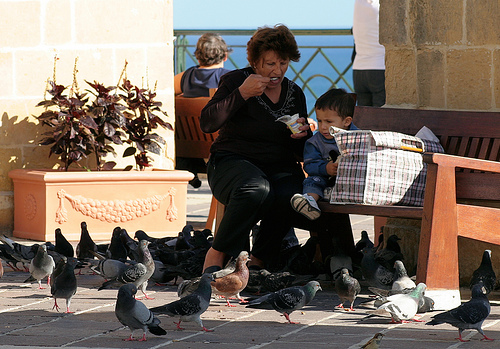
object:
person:
[289, 87, 365, 220]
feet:
[203, 248, 223, 276]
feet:
[199, 325, 215, 331]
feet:
[479, 335, 492, 339]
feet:
[123, 337, 138, 342]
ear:
[343, 115, 351, 126]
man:
[180, 31, 233, 99]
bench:
[175, 95, 222, 158]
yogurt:
[280, 112, 302, 137]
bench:
[214, 104, 499, 309]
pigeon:
[114, 280, 167, 342]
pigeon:
[240, 279, 323, 324]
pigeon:
[330, 265, 361, 310]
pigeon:
[210, 254, 252, 307]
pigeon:
[22, 242, 57, 290]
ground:
[0, 178, 499, 348]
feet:
[289, 194, 326, 220]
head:
[246, 25, 301, 90]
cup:
[275, 114, 307, 135]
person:
[198, 25, 311, 274]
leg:
[207, 160, 271, 251]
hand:
[239, 74, 267, 99]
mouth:
[270, 75, 280, 82]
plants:
[82, 76, 128, 173]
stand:
[13, 167, 195, 243]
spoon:
[269, 74, 276, 77]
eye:
[278, 60, 288, 64]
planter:
[11, 166, 195, 241]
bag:
[328, 125, 448, 208]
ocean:
[172, 32, 354, 133]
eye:
[266, 63, 275, 66]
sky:
[173, 0, 356, 30]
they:
[200, 24, 314, 277]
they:
[289, 79, 369, 229]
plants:
[123, 78, 173, 171]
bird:
[354, 281, 429, 325]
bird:
[148, 271, 220, 332]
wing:
[383, 297, 421, 322]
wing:
[216, 274, 244, 293]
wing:
[151, 295, 201, 313]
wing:
[258, 290, 307, 313]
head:
[313, 88, 361, 141]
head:
[194, 31, 230, 69]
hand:
[292, 110, 310, 137]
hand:
[325, 160, 345, 176]